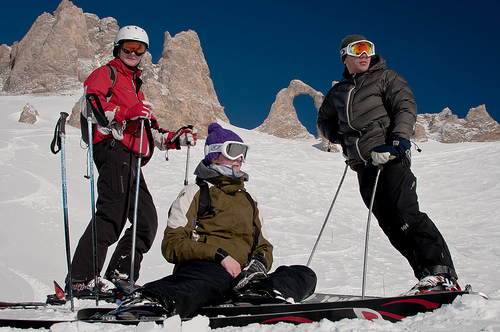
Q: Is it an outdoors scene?
A: Yes, it is outdoors.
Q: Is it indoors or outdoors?
A: It is outdoors.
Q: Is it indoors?
A: No, it is outdoors.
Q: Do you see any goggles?
A: Yes, there are goggles.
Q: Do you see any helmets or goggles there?
A: Yes, there are goggles.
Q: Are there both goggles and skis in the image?
A: Yes, there are both goggles and skis.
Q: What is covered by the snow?
A: The mountain is covered by the snow.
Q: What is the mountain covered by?
A: The mountain is covered by the snow.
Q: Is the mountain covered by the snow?
A: Yes, the mountain is covered by the snow.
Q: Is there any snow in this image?
A: Yes, there is snow.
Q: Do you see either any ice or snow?
A: Yes, there is snow.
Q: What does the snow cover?
A: The snow covers the mountain.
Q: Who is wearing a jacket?
A: The man is wearing a jacket.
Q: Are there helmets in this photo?
A: Yes, there is a helmet.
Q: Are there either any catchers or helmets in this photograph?
A: Yes, there is a helmet.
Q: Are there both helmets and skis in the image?
A: Yes, there are both a helmet and a ski.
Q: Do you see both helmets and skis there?
A: Yes, there are both a helmet and a ski.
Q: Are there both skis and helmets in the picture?
A: Yes, there are both a helmet and a ski.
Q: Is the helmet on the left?
A: Yes, the helmet is on the left of the image.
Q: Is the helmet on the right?
A: No, the helmet is on the left of the image.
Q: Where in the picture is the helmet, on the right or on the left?
A: The helmet is on the left of the image.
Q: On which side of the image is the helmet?
A: The helmet is on the left of the image.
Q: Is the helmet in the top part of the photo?
A: Yes, the helmet is in the top of the image.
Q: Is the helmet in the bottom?
A: No, the helmet is in the top of the image.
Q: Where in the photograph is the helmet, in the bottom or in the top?
A: The helmet is in the top of the image.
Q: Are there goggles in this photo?
A: Yes, there are goggles.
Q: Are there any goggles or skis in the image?
A: Yes, there are goggles.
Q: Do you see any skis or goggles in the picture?
A: Yes, there are goggles.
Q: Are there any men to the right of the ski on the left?
A: Yes, there is a man to the right of the ski.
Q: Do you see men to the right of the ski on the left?
A: Yes, there is a man to the right of the ski.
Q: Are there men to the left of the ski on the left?
A: No, the man is to the right of the ski.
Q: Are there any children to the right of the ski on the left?
A: No, there is a man to the right of the ski.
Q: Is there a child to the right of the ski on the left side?
A: No, there is a man to the right of the ski.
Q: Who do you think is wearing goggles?
A: The man is wearing goggles.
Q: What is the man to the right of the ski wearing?
A: The man is wearing goggles.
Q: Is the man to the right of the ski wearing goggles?
A: Yes, the man is wearing goggles.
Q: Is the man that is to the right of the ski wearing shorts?
A: No, the man is wearing goggles.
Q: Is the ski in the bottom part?
A: Yes, the ski is in the bottom of the image.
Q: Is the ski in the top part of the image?
A: No, the ski is in the bottom of the image.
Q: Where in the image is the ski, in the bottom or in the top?
A: The ski is in the bottom of the image.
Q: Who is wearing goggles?
A: The man is wearing goggles.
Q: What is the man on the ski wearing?
A: The man is wearing goggles.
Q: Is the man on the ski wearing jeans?
A: No, the man is wearing goggles.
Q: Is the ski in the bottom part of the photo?
A: Yes, the ski is in the bottom of the image.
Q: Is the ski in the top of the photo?
A: No, the ski is in the bottom of the image.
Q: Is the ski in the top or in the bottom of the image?
A: The ski is in the bottom of the image.